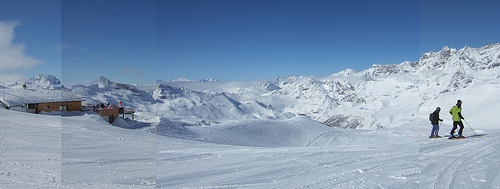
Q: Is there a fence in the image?
A: No, there are no fences.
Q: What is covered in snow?
A: The ground is covered in snow.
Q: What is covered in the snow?
A: The ground is covered in snow.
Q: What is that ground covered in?
A: The ground is covered in snow.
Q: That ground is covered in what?
A: The ground is covered in snow.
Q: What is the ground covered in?
A: The ground is covered in snow.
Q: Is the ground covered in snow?
A: Yes, the ground is covered in snow.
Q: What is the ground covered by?
A: The ground is covered by the snow.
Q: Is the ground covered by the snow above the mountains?
A: Yes, the ground is covered by the snow.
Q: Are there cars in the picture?
A: No, there are no cars.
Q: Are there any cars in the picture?
A: No, there are no cars.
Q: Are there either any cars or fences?
A: No, there are no cars or fences.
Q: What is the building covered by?
A: The building is covered by the snow.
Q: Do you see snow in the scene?
A: Yes, there is snow.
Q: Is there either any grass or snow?
A: Yes, there is snow.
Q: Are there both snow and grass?
A: No, there is snow but no grass.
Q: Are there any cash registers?
A: No, there are no cash registers.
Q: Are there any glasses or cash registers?
A: No, there are no cash registers or glasses.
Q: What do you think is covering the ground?
A: The snow is covering the ground.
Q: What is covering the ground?
A: The snow is covering the ground.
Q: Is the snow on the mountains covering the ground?
A: Yes, the snow is covering the ground.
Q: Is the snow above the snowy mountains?
A: Yes, the snow is above the mountains.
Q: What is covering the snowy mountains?
A: The snow is covering the mountains.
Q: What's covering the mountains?
A: The snow is covering the mountains.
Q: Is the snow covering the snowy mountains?
A: Yes, the snow is covering the mountains.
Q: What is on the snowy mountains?
A: The snow is on the mountains.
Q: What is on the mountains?
A: The snow is on the mountains.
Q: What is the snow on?
A: The snow is on the mountains.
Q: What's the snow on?
A: The snow is on the mountains.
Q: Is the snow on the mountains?
A: Yes, the snow is on the mountains.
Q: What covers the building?
A: The snow covers the building.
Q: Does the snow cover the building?
A: Yes, the snow covers the building.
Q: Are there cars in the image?
A: No, there are no cars.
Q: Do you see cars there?
A: No, there are no cars.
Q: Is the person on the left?
A: No, the person is on the right of the image.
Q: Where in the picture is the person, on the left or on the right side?
A: The person is on the right of the image.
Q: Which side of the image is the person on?
A: The person is on the right of the image.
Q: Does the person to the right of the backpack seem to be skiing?
A: Yes, the person is skiing.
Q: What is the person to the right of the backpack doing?
A: The person is skiing.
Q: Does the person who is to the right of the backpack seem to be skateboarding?
A: No, the person is skiing.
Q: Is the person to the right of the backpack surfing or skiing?
A: The person is skiing.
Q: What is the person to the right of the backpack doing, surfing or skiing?
A: The person is skiing.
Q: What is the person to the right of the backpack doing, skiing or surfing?
A: The person is skiing.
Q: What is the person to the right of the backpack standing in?
A: The person is standing in the snow.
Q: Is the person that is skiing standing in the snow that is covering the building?
A: Yes, the person is standing in the snow.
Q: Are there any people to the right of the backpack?
A: Yes, there is a person to the right of the backpack.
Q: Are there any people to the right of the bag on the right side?
A: Yes, there is a person to the right of the backpack.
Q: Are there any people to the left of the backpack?
A: No, the person is to the right of the backpack.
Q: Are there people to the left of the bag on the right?
A: No, the person is to the right of the backpack.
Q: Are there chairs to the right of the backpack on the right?
A: No, there is a person to the right of the backpack.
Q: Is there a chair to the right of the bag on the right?
A: No, there is a person to the right of the backpack.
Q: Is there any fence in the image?
A: No, there are no fences.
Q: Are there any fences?
A: No, there are no fences.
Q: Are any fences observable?
A: No, there are no fences.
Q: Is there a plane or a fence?
A: No, there are no fences or airplanes.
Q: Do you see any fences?
A: No, there are no fences.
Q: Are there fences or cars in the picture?
A: No, there are no fences or cars.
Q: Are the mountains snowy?
A: Yes, the mountains are snowy.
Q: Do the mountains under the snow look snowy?
A: Yes, the mountains are snowy.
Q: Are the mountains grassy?
A: No, the mountains are snowy.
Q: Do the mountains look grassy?
A: No, the mountains are snowy.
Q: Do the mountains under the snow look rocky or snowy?
A: The mountains are snowy.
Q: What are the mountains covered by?
A: The mountains are covered by the snow.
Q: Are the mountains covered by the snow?
A: Yes, the mountains are covered by the snow.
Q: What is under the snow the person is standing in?
A: The mountains are under the snow.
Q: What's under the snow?
A: The mountains are under the snow.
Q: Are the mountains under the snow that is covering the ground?
A: Yes, the mountains are under the snow.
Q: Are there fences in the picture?
A: No, there are no fences.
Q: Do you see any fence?
A: No, there are no fences.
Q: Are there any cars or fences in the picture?
A: No, there are no fences or cars.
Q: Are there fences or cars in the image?
A: No, there are no fences or cars.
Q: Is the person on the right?
A: Yes, the person is on the right of the image.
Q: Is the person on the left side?
A: No, the person is on the right of the image.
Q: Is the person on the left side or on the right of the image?
A: The person is on the right of the image.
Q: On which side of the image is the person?
A: The person is on the right of the image.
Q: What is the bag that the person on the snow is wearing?
A: The bag is a backpack.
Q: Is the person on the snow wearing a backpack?
A: Yes, the person is wearing a backpack.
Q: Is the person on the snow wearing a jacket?
A: Yes, the person is wearing a jacket.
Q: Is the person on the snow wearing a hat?
A: No, the person is wearing a jacket.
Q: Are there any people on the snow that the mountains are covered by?
A: Yes, there is a person on the snow.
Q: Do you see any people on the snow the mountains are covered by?
A: Yes, there is a person on the snow.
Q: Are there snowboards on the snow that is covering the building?
A: No, there is a person on the snow.